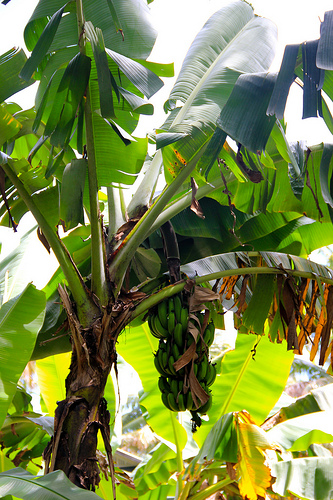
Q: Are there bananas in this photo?
A: Yes, there is a banana.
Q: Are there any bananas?
A: Yes, there is a banana.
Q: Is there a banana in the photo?
A: Yes, there is a banana.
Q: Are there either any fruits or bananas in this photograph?
A: Yes, there is a banana.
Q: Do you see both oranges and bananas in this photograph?
A: No, there is a banana but no oranges.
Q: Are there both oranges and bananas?
A: No, there is a banana but no oranges.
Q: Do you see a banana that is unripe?
A: Yes, there is an unripe banana.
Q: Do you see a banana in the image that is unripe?
A: Yes, there is a banana that is unripe.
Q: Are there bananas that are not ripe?
A: Yes, there is a unripe banana.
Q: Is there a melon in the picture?
A: No, there are no melons.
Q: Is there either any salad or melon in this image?
A: No, there are no melons or salad.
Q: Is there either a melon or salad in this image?
A: No, there are no melons or salad.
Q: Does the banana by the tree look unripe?
A: Yes, the banana is unripe.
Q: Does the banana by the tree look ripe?
A: No, the banana is unripe.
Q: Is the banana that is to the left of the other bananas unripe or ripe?
A: The banana is unripe.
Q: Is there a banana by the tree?
A: Yes, there is a banana by the tree.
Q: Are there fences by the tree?
A: No, there is a banana by the tree.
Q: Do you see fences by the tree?
A: No, there is a banana by the tree.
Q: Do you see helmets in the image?
A: No, there are no helmets.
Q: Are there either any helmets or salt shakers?
A: No, there are no helmets or salt shakers.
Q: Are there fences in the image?
A: No, there are no fences.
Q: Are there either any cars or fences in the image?
A: No, there are no fences or cars.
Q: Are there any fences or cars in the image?
A: No, there are no fences or cars.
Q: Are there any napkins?
A: No, there are no napkins.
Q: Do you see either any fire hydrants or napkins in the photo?
A: No, there are no napkins or fire hydrants.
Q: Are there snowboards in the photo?
A: No, there are no snowboards.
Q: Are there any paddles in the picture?
A: No, there are no paddles.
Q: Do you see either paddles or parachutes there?
A: No, there are no paddles or parachutes.